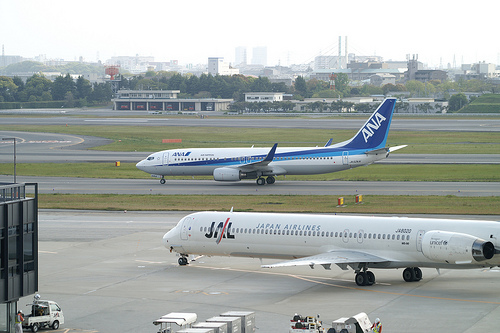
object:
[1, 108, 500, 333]
airport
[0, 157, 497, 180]
grass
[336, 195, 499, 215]
grass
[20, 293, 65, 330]
truck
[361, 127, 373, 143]
letters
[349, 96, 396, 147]
tail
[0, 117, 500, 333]
ground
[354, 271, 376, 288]
wheels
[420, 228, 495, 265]
engine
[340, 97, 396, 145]
blue tail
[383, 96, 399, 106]
terminal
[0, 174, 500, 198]
tarmac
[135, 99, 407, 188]
plane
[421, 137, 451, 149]
greenfield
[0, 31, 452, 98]
downtown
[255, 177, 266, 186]
wheel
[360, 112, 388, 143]
ana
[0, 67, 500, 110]
scene outside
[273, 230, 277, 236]
windows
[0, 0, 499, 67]
sky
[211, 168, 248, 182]
engine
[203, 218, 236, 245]
logo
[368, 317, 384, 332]
worker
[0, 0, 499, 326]
photograph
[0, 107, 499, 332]
runway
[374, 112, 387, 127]
letters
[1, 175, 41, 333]
luggage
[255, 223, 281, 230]
writing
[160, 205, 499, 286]
airplane